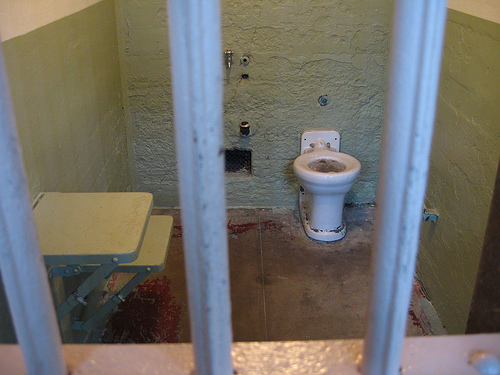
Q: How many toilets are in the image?
A: One.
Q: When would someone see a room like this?
A: Prison.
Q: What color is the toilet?
A: White.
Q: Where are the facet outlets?
A: On the wall.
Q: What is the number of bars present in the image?
A: Three.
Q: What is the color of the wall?
A: Green.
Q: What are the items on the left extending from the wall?
A: Tables.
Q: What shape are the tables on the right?
A: Square.